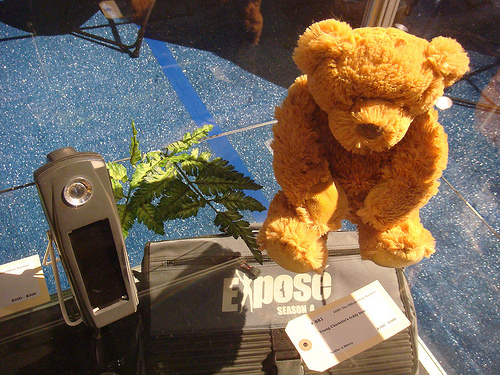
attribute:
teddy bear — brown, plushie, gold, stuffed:
[257, 17, 468, 266]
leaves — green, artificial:
[101, 118, 265, 265]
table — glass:
[1, 118, 499, 374]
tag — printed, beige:
[284, 280, 411, 372]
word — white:
[222, 271, 333, 312]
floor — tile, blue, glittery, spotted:
[2, 31, 237, 156]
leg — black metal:
[133, 3, 155, 59]